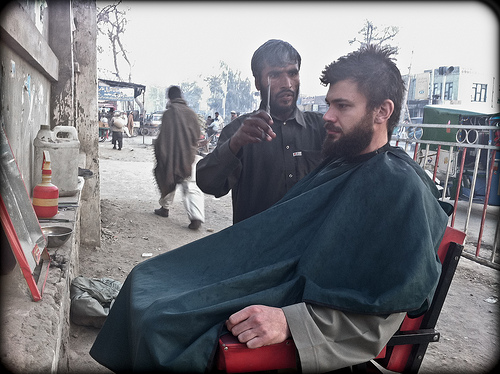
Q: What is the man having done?
A: Hair cut.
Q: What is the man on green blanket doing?
A: Getting hair cut.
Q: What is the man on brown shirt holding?
A: Scissors.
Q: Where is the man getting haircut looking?
A: Mirror.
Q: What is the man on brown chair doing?
A: Hair Cutting.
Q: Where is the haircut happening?
A: On the Street.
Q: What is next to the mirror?
A: Steel Bowl.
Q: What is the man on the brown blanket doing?
A: Walking Away.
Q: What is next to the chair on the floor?
A: A sack.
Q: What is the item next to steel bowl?
A: Water Spray.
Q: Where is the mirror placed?
A: On the wall.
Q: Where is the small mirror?
A: On the ledge.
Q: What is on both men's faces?
A: Facial hair.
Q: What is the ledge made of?
A: Concrete.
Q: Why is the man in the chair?
A: Getting a haircut.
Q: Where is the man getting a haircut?
A: On the sidewalk.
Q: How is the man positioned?
A: Sitting.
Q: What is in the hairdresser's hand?
A: Scissors.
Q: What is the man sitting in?
A: A red chair.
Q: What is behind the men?
A: Buildings.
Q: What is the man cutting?
A: His hair.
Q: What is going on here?
A: Haircut.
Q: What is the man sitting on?
A: Chair.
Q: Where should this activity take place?
A: Salon.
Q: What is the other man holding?
A: Scissors.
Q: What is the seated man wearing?
A: Cape.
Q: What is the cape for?
A: Protection.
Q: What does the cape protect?
A: Clothes from hair.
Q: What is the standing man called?
A: Barber.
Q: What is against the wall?
A: Mirror.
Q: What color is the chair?
A: Red.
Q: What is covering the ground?
A: Dirt.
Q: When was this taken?
A: Daytime.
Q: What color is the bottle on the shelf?
A: Red and yellow.